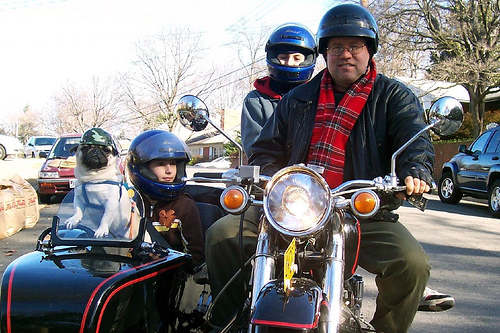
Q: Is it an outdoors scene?
A: Yes, it is outdoors.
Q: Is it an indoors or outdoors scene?
A: It is outdoors.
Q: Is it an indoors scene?
A: No, it is outdoors.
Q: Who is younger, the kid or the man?
A: The kid is younger than the man.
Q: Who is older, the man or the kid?
A: The man is older than the kid.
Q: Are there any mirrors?
A: Yes, there is a mirror.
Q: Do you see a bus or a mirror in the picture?
A: Yes, there is a mirror.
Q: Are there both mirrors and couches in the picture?
A: No, there is a mirror but no couches.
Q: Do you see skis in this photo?
A: No, there are no skis.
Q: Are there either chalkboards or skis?
A: No, there are no skis or chalkboards.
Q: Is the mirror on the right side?
A: Yes, the mirror is on the right of the image.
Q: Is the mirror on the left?
A: No, the mirror is on the right of the image.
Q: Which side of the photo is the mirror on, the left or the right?
A: The mirror is on the right of the image.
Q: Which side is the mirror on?
A: The mirror is on the right of the image.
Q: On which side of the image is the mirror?
A: The mirror is on the right of the image.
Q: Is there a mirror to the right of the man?
A: Yes, there is a mirror to the right of the man.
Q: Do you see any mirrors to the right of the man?
A: Yes, there is a mirror to the right of the man.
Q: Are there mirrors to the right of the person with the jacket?
A: Yes, there is a mirror to the right of the man.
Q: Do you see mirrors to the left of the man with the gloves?
A: No, the mirror is to the right of the man.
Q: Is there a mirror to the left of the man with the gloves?
A: No, the mirror is to the right of the man.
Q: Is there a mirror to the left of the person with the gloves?
A: No, the mirror is to the right of the man.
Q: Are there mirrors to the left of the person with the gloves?
A: No, the mirror is to the right of the man.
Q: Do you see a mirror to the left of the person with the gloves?
A: No, the mirror is to the right of the man.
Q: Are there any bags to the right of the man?
A: No, there is a mirror to the right of the man.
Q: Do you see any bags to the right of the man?
A: No, there is a mirror to the right of the man.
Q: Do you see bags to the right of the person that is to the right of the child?
A: No, there is a mirror to the right of the man.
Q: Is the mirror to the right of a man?
A: Yes, the mirror is to the right of a man.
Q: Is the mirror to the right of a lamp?
A: No, the mirror is to the right of a man.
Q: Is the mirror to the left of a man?
A: No, the mirror is to the right of a man.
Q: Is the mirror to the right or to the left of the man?
A: The mirror is to the right of the man.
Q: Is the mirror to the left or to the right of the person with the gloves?
A: The mirror is to the right of the man.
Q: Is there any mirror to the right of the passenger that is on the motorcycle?
A: Yes, there is a mirror to the right of the passenger.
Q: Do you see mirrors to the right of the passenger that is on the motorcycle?
A: Yes, there is a mirror to the right of the passenger.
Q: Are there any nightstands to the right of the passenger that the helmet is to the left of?
A: No, there is a mirror to the right of the passenger.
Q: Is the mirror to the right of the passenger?
A: Yes, the mirror is to the right of the passenger.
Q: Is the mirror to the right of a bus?
A: No, the mirror is to the right of the passenger.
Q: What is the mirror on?
A: The mirror is on the motorbike.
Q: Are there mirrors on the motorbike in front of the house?
A: Yes, there is a mirror on the motorcycle.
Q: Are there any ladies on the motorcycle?
A: No, there is a mirror on the motorcycle.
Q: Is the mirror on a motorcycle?
A: Yes, the mirror is on a motorcycle.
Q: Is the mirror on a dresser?
A: No, the mirror is on a motorcycle.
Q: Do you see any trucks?
A: No, there are no trucks.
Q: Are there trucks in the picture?
A: No, there are no trucks.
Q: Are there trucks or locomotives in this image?
A: No, there are no trucks or locomotives.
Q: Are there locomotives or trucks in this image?
A: No, there are no trucks or locomotives.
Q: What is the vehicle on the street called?
A: The vehicle is a SUV.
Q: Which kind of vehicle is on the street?
A: The vehicle is a SUV.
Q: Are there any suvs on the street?
A: Yes, there is a SUV on the street.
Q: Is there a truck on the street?
A: No, there is a SUV on the street.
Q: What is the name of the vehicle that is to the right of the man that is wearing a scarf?
A: The vehicle is a SUV.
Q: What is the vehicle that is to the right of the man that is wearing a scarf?
A: The vehicle is a SUV.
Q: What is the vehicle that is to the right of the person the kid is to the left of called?
A: The vehicle is a SUV.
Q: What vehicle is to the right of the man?
A: The vehicle is a SUV.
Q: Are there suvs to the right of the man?
A: Yes, there is a SUV to the right of the man.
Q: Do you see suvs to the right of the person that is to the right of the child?
A: Yes, there is a SUV to the right of the man.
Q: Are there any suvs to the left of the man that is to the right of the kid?
A: No, the SUV is to the right of the man.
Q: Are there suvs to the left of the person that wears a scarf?
A: No, the SUV is to the right of the man.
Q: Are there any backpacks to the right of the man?
A: No, there is a SUV to the right of the man.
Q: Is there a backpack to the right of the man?
A: No, there is a SUV to the right of the man.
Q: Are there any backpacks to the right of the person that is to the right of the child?
A: No, there is a SUV to the right of the man.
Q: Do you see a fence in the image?
A: No, there are no fences.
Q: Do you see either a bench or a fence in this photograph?
A: No, there are no fences or benches.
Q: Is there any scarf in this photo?
A: Yes, there is a scarf.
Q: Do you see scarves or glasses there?
A: Yes, there is a scarf.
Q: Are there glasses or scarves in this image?
A: Yes, there is a scarf.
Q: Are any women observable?
A: No, there are no women.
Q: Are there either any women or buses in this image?
A: No, there are no women or buses.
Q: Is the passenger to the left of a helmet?
A: Yes, the passenger is to the left of a helmet.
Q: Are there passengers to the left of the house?
A: Yes, there is a passenger to the left of the house.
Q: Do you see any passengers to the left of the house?
A: Yes, there is a passenger to the left of the house.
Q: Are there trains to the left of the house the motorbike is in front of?
A: No, there is a passenger to the left of the house.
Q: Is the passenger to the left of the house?
A: Yes, the passenger is to the left of the house.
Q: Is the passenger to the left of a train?
A: No, the passenger is to the left of the house.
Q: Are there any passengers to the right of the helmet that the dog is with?
A: Yes, there is a passenger to the right of the helmet.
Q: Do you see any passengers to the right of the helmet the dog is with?
A: Yes, there is a passenger to the right of the helmet.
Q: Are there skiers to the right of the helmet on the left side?
A: No, there is a passenger to the right of the helmet.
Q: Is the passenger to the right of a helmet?
A: Yes, the passenger is to the right of a helmet.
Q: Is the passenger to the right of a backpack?
A: No, the passenger is to the right of a helmet.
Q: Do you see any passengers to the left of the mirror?
A: Yes, there is a passenger to the left of the mirror.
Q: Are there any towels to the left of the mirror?
A: No, there is a passenger to the left of the mirror.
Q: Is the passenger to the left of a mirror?
A: Yes, the passenger is to the left of a mirror.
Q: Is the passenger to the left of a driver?
A: No, the passenger is to the left of a mirror.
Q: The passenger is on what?
A: The passenger is on the motorbike.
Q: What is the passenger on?
A: The passenger is on the motorbike.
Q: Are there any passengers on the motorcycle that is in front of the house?
A: Yes, there is a passenger on the motorcycle.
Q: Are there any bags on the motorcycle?
A: No, there is a passenger on the motorcycle.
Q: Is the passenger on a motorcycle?
A: Yes, the passenger is on a motorcycle.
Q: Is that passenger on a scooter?
A: No, the passenger is on a motorcycle.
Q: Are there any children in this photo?
A: Yes, there is a child.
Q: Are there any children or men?
A: Yes, there is a child.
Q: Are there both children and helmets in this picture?
A: Yes, there are both a child and a helmet.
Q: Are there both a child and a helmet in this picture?
A: Yes, there are both a child and a helmet.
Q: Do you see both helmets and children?
A: Yes, there are both a child and a helmet.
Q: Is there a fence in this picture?
A: No, there are no fences.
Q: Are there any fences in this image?
A: No, there are no fences.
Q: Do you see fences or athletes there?
A: No, there are no fences or athletes.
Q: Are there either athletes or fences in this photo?
A: No, there are no fences or athletes.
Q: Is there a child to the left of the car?
A: No, the child is to the right of the car.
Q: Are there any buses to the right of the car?
A: No, there is a child to the right of the car.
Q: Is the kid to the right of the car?
A: Yes, the kid is to the right of the car.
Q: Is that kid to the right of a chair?
A: No, the kid is to the right of the car.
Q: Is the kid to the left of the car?
A: No, the kid is to the right of the car.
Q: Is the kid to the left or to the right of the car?
A: The kid is to the right of the car.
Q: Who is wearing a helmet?
A: The child is wearing a helmet.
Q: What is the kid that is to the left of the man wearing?
A: The child is wearing a helmet.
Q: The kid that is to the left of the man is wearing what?
A: The child is wearing a helmet.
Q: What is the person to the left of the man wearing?
A: The child is wearing a helmet.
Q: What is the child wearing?
A: The child is wearing a helmet.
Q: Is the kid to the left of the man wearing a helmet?
A: Yes, the kid is wearing a helmet.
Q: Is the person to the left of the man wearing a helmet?
A: Yes, the kid is wearing a helmet.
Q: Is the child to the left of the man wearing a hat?
A: No, the kid is wearing a helmet.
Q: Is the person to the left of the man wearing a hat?
A: No, the kid is wearing a helmet.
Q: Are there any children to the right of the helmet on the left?
A: Yes, there is a child to the right of the helmet.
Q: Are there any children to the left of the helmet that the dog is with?
A: No, the child is to the right of the helmet.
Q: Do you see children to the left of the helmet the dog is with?
A: No, the child is to the right of the helmet.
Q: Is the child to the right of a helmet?
A: Yes, the child is to the right of a helmet.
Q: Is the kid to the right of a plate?
A: No, the kid is to the right of a helmet.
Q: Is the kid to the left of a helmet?
A: No, the kid is to the right of a helmet.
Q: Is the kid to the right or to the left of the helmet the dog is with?
A: The kid is to the right of the helmet.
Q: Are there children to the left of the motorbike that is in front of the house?
A: Yes, there is a child to the left of the motorcycle.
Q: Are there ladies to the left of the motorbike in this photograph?
A: No, there is a child to the left of the motorbike.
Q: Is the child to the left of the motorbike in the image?
A: Yes, the child is to the left of the motorbike.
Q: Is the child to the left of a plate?
A: No, the child is to the left of the motorbike.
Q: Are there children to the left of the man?
A: Yes, there is a child to the left of the man.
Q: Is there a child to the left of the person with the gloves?
A: Yes, there is a child to the left of the man.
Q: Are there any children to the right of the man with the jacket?
A: No, the child is to the left of the man.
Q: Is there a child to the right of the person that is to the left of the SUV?
A: No, the child is to the left of the man.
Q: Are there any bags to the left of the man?
A: No, there is a child to the left of the man.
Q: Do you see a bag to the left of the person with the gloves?
A: No, there is a child to the left of the man.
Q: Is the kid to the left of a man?
A: Yes, the kid is to the left of a man.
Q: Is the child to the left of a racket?
A: No, the child is to the left of a man.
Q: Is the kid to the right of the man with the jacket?
A: No, the kid is to the left of the man.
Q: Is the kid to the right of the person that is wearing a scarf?
A: No, the kid is to the left of the man.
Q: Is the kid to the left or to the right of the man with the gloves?
A: The kid is to the left of the man.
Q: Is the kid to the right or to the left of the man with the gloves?
A: The kid is to the left of the man.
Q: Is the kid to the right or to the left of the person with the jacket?
A: The kid is to the left of the man.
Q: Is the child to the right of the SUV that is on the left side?
A: Yes, the child is to the right of the SUV.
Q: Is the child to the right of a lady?
A: No, the child is to the right of the SUV.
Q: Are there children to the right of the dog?
A: Yes, there is a child to the right of the dog.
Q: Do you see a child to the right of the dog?
A: Yes, there is a child to the right of the dog.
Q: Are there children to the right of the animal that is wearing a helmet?
A: Yes, there is a child to the right of the dog.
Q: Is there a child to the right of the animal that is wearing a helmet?
A: Yes, there is a child to the right of the dog.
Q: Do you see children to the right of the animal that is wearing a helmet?
A: Yes, there is a child to the right of the dog.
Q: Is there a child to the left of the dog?
A: No, the child is to the right of the dog.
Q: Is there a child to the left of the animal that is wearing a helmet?
A: No, the child is to the right of the dog.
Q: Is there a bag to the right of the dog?
A: No, there is a child to the right of the dog.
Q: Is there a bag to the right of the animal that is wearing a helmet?
A: No, there is a child to the right of the dog.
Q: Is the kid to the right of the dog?
A: Yes, the kid is to the right of the dog.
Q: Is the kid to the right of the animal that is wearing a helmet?
A: Yes, the kid is to the right of the dog.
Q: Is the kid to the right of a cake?
A: No, the kid is to the right of the dog.